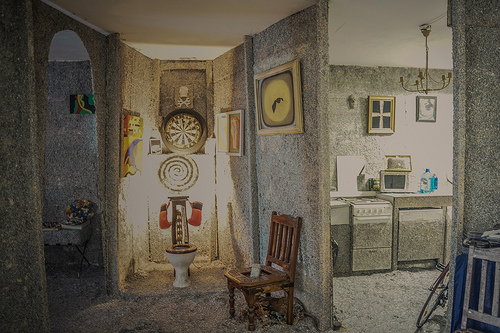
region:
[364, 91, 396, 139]
picture in a frame hanging on the wall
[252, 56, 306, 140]
picture in a frame hanging on the wall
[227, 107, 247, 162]
picture in a frame hanging on the wall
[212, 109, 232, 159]
picture in a frame hanging on the wall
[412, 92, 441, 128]
picture in a frame hanging on the wall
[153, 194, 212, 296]
toilet with a brown seat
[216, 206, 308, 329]
chair made out of brown wood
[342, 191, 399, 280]
small electric stove colored white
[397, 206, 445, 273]
white dishwasher with mud on the front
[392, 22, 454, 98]
old chandelier with no bulbs in it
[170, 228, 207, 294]
toilet seat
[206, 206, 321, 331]
wooden chair next to the wall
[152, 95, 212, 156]
dart board on the wall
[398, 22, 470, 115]
light fixture in the kitchen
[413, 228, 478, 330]
bike against the wall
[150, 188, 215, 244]
red boxing gloves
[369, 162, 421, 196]
microwave on the counter top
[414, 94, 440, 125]
picture on the wall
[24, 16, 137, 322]
arch door way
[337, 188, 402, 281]
stove in the kitchen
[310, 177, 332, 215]
part of an edge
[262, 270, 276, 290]
part of a chair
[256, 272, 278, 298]
part of a chair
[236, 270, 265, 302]
eddge of a chair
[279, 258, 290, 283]
part f a chair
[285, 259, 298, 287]
part f a woor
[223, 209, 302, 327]
A chair by the wall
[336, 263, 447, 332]
The floor of the kitchen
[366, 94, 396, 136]
A picture hanging on the wall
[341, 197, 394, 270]
A stove in the kitchen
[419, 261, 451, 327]
The tire of a bicycle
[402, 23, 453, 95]
A light fixture hanging from the ceiling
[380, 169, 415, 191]
A microwave in the kitchen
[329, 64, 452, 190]
A wall in the kitchen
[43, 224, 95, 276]
A table in a dark room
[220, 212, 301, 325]
wooden chair against the wall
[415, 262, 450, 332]
bicycle in the kitchen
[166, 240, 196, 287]
white toilet bowl in the hallway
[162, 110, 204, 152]
dartboard hanging above the toilet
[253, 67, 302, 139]
brown, yellow, and black painting above the chair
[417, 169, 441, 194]
blue bottles on the kitchen counter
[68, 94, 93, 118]
black, green, yellow, and red painting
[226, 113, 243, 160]
yellow and orange painting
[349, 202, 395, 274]
white and gray stove in the kitchen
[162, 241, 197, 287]
Toilet below the swirl.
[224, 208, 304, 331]
Chair beside the wall.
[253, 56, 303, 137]
Picture above the chair.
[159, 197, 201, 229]
Gloves by the toilet.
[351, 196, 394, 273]
Stove in the kitchen.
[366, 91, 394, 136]
Picture on the wall.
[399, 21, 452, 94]
Light hanging from the ceiling.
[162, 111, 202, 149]
Dart board above the toilet.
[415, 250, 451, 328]
Bike in the kitchen.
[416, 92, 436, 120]
Picture on the wall.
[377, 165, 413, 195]
a micowave on the counter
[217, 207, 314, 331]
a wooden chair in the room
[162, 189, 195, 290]
a toilet in the bathroom